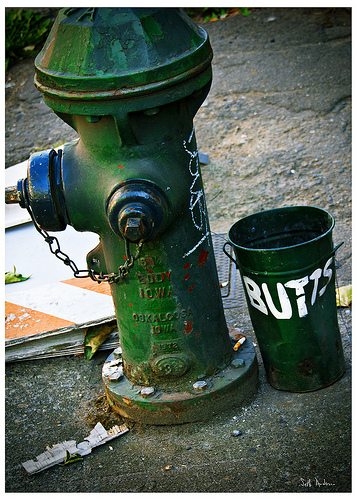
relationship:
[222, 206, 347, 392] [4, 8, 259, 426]
trash can next to hydrant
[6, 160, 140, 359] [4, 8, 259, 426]
construction stand near hydrant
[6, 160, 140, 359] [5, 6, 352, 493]
construction stand on sidewalk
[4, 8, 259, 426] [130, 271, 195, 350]
hydrant has writing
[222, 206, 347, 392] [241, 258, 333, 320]
trash can has writing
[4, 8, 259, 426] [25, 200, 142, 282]
hydrant has chain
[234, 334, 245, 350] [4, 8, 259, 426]
cigarette at base of hydrant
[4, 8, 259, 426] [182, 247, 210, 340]
hydrant has rust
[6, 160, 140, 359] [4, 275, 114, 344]
construction stand has stripes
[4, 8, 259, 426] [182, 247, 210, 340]
hydrant has spots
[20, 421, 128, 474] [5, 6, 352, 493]
paper on sidewalk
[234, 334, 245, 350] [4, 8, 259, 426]
cigarette lays on hydrant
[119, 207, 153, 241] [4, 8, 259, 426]
bolt on hydrant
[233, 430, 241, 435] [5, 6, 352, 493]
pebble on sidewalk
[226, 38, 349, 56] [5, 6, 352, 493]
crack in sidewalk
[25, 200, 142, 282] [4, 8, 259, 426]
chain on hydrant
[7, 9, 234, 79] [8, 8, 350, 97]
bush in background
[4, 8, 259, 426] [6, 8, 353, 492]
hydrant on sidewalk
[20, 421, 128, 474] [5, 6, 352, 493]
trash on sidewalk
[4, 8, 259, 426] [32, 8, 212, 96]
hydrant has top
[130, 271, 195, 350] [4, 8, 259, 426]
writing on hydrant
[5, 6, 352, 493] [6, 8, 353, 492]
sidewalk on road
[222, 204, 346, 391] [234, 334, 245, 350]
trash can for cigarette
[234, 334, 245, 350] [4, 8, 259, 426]
cigarette on hydrant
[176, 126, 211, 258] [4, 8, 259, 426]
chalk on hydrant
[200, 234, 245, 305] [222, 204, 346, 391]
man hole behind trash can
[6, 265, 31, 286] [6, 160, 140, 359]
leaves laying on construction stand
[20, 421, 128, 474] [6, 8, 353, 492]
garbage on sidewalk